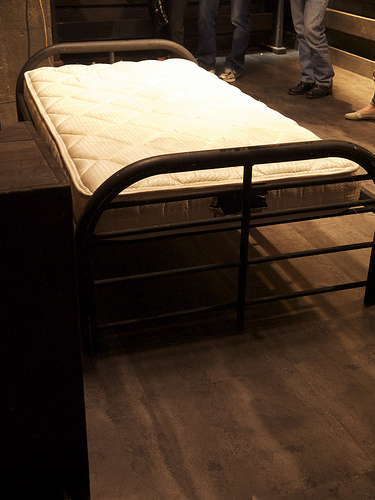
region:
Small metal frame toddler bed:
[7, 40, 373, 330]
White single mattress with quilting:
[36, 65, 256, 137]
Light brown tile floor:
[107, 366, 362, 488]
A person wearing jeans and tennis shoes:
[198, 8, 249, 85]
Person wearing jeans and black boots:
[289, 15, 337, 107]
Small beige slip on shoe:
[342, 98, 374, 126]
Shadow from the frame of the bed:
[225, 228, 340, 331]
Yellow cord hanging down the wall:
[34, 1, 53, 62]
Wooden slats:
[331, 6, 372, 76]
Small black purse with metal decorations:
[143, 0, 173, 29]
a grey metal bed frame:
[20, 36, 373, 248]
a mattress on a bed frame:
[18, 55, 362, 213]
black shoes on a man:
[290, 68, 342, 110]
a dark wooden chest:
[0, 106, 77, 218]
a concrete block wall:
[0, 0, 53, 123]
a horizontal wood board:
[307, 6, 372, 41]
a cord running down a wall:
[32, 0, 59, 67]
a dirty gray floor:
[78, 45, 374, 497]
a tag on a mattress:
[205, 181, 271, 219]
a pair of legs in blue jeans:
[195, 1, 254, 76]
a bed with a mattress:
[7, 21, 371, 233]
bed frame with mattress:
[7, 21, 370, 252]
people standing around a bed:
[17, 31, 345, 242]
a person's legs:
[287, 0, 369, 127]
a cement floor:
[62, 297, 364, 496]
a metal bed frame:
[66, 147, 372, 335]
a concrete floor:
[79, 306, 349, 474]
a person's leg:
[263, 0, 344, 106]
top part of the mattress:
[42, 71, 170, 101]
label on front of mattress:
[211, 191, 274, 215]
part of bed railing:
[135, 152, 260, 316]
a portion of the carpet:
[132, 403, 300, 454]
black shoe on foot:
[310, 83, 328, 100]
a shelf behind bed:
[61, 21, 141, 36]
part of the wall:
[11, 5, 36, 44]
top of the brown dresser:
[3, 130, 52, 187]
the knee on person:
[229, 12, 249, 30]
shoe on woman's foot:
[342, 104, 373, 120]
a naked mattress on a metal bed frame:
[11, 37, 374, 313]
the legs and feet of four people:
[150, 3, 373, 127]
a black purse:
[145, 2, 167, 28]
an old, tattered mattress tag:
[211, 188, 271, 220]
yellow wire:
[30, 0, 65, 66]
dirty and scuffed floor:
[80, 349, 373, 479]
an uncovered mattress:
[13, 59, 370, 239]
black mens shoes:
[285, 76, 335, 101]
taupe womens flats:
[339, 101, 373, 124]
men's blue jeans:
[288, 0, 341, 86]